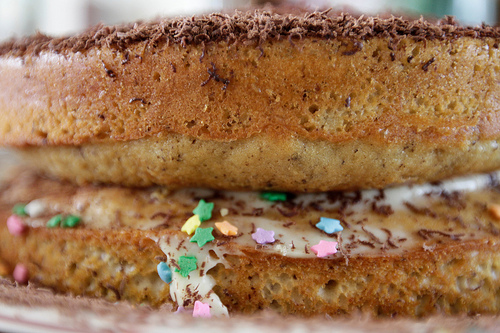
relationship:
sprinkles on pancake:
[151, 198, 345, 320] [0, 2, 500, 317]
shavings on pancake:
[101, 38, 166, 57] [138, 69, 331, 186]